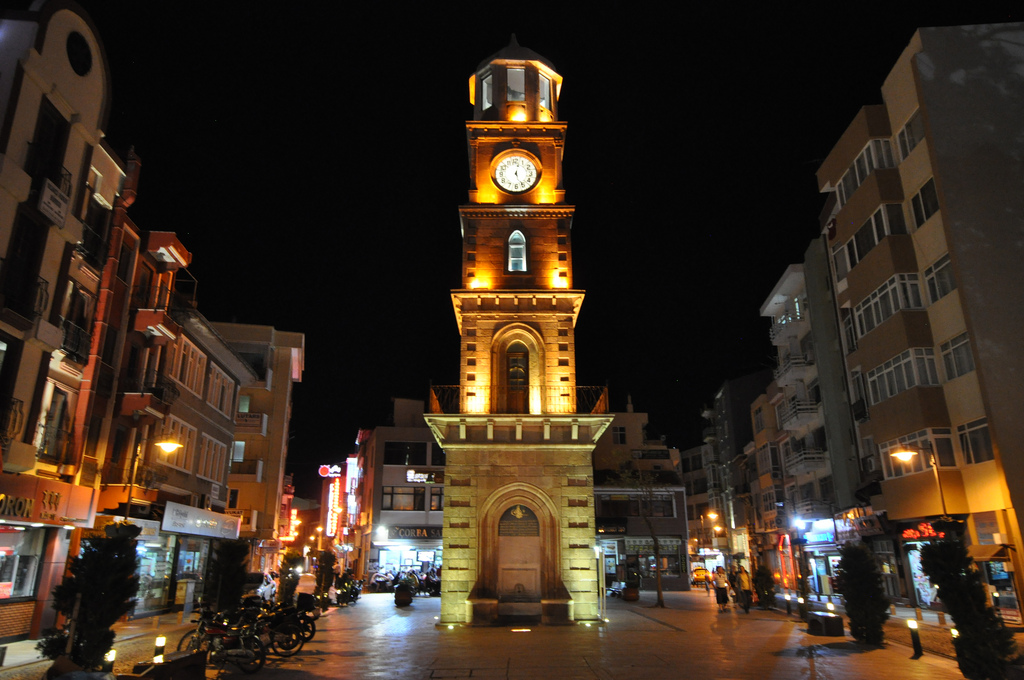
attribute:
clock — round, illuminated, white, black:
[468, 147, 544, 206]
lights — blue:
[339, 511, 432, 630]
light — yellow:
[881, 440, 927, 482]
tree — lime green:
[24, 498, 146, 680]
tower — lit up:
[424, 55, 613, 628]